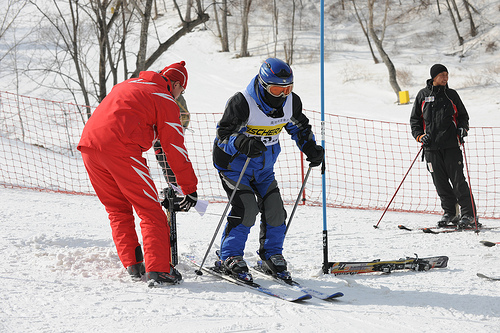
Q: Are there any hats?
A: Yes, there is a hat.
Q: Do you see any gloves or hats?
A: Yes, there is a hat.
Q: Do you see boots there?
A: Yes, there are boots.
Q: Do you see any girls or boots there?
A: Yes, there are boots.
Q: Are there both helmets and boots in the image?
A: Yes, there are both boots and a helmet.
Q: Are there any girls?
A: No, there are no girls.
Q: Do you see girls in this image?
A: No, there are no girls.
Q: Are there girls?
A: No, there are no girls.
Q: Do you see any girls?
A: No, there are no girls.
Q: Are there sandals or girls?
A: No, there are no girls or sandals.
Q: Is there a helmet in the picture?
A: Yes, there is a helmet.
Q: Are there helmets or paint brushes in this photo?
A: Yes, there is a helmet.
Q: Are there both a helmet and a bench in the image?
A: No, there is a helmet but no benches.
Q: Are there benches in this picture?
A: No, there are no benches.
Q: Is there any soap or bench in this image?
A: No, there are no benches or soaps.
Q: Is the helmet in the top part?
A: Yes, the helmet is in the top of the image.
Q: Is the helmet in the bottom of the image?
A: No, the helmet is in the top of the image.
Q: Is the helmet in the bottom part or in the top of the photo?
A: The helmet is in the top of the image.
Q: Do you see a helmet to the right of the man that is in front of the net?
A: Yes, there is a helmet to the right of the man.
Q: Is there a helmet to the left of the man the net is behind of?
A: No, the helmet is to the right of the man.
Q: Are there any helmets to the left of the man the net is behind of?
A: No, the helmet is to the right of the man.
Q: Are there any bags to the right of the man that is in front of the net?
A: No, there is a helmet to the right of the man.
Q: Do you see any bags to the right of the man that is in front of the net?
A: No, there is a helmet to the right of the man.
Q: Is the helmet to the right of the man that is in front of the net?
A: Yes, the helmet is to the right of the man.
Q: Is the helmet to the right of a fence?
A: No, the helmet is to the right of the man.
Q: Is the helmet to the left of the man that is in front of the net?
A: No, the helmet is to the right of the man.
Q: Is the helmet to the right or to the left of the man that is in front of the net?
A: The helmet is to the right of the man.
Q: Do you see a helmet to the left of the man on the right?
A: Yes, there is a helmet to the left of the man.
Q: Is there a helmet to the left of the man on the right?
A: Yes, there is a helmet to the left of the man.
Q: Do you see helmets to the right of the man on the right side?
A: No, the helmet is to the left of the man.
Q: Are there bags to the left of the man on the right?
A: No, there is a helmet to the left of the man.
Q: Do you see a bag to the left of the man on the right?
A: No, there is a helmet to the left of the man.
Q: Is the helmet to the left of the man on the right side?
A: Yes, the helmet is to the left of the man.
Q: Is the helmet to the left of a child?
A: No, the helmet is to the left of the man.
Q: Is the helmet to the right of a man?
A: No, the helmet is to the left of a man.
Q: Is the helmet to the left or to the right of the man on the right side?
A: The helmet is to the left of the man.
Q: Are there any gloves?
A: Yes, there are gloves.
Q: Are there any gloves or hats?
A: Yes, there are gloves.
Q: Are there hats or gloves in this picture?
A: Yes, there are gloves.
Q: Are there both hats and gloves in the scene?
A: Yes, there are both gloves and a hat.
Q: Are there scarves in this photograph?
A: No, there are no scarves.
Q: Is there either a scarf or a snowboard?
A: No, there are no scarves or snowboards.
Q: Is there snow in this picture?
A: Yes, there is snow.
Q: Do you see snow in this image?
A: Yes, there is snow.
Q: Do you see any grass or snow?
A: Yes, there is snow.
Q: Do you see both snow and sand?
A: No, there is snow but no sand.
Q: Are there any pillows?
A: No, there are no pillows.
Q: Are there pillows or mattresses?
A: No, there are no pillows or mattresses.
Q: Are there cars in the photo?
A: No, there are no cars.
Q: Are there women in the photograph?
A: No, there are no women.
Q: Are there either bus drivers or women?
A: No, there are no women or bus drivers.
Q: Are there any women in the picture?
A: No, there are no women.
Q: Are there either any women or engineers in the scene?
A: No, there are no women or engineers.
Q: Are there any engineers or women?
A: No, there are no women or engineers.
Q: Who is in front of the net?
A: The man is in front of the net.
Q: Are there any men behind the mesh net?
A: No, the man is in front of the net.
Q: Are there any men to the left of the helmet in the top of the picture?
A: Yes, there is a man to the left of the helmet.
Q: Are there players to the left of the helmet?
A: No, there is a man to the left of the helmet.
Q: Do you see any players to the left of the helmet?
A: No, there is a man to the left of the helmet.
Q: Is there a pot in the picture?
A: No, there are no pots.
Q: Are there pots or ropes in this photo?
A: No, there are no pots or ropes.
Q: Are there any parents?
A: No, there are no parents.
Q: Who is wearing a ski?
A: The man is wearing a ski.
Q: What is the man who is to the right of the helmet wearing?
A: The man is wearing a ski.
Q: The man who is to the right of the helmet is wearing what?
A: The man is wearing a ski.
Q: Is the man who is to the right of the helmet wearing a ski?
A: Yes, the man is wearing a ski.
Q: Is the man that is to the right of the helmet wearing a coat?
A: No, the man is wearing a ski.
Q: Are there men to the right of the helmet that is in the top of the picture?
A: Yes, there is a man to the right of the helmet.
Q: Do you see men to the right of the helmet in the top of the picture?
A: Yes, there is a man to the right of the helmet.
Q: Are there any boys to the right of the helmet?
A: No, there is a man to the right of the helmet.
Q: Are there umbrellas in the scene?
A: No, there are no umbrellas.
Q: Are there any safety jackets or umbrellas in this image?
A: No, there are no umbrellas or safety jackets.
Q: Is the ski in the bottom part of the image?
A: Yes, the ski is in the bottom of the image.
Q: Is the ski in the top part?
A: No, the ski is in the bottom of the image.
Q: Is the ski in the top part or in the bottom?
A: The ski is in the bottom of the image.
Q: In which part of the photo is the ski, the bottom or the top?
A: The ski is in the bottom of the image.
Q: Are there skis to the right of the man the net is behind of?
A: Yes, there is a ski to the right of the man.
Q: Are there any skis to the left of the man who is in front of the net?
A: No, the ski is to the right of the man.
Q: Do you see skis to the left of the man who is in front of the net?
A: No, the ski is to the right of the man.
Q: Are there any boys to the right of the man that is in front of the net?
A: No, there is a ski to the right of the man.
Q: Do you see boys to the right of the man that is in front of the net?
A: No, there is a ski to the right of the man.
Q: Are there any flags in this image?
A: No, there are no flags.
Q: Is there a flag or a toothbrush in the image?
A: No, there are no flags or toothbrushes.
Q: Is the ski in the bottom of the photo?
A: Yes, the ski is in the bottom of the image.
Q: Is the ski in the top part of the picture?
A: No, the ski is in the bottom of the image.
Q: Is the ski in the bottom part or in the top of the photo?
A: The ski is in the bottom of the image.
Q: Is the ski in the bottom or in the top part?
A: The ski is in the bottom of the image.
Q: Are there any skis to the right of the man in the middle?
A: Yes, there is a ski to the right of the man.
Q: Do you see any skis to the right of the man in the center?
A: Yes, there is a ski to the right of the man.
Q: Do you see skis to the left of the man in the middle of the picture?
A: No, the ski is to the right of the man.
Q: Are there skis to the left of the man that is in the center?
A: No, the ski is to the right of the man.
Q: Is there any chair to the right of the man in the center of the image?
A: No, there is a ski to the right of the man.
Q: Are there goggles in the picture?
A: Yes, there are goggles.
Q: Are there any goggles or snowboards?
A: Yes, there are goggles.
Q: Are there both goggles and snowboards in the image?
A: No, there are goggles but no snowboards.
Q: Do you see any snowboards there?
A: No, there are no snowboards.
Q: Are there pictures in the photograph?
A: No, there are no pictures.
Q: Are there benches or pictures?
A: No, there are no pictures or benches.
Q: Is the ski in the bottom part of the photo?
A: Yes, the ski is in the bottom of the image.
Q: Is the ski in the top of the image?
A: No, the ski is in the bottom of the image.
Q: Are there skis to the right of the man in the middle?
A: Yes, there is a ski to the right of the man.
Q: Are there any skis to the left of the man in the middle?
A: No, the ski is to the right of the man.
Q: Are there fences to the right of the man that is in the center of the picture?
A: No, there is a ski to the right of the man.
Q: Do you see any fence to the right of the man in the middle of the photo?
A: No, there is a ski to the right of the man.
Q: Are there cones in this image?
A: No, there are no cones.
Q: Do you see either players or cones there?
A: No, there are no cones or players.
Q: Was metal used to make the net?
A: No, the net is made of mesh.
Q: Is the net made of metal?
A: No, the net is made of mesh.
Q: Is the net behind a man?
A: Yes, the net is behind a man.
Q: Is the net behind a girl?
A: No, the net is behind a man.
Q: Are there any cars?
A: No, there are no cars.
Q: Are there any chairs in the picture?
A: No, there are no chairs.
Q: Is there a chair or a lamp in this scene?
A: No, there are no chairs or lamps.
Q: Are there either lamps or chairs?
A: No, there are no chairs or lamps.